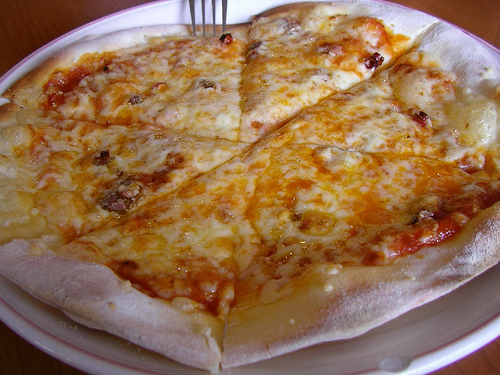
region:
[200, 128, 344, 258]
greasy pizza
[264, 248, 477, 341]
crust on a pizza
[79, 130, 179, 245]
burnt cheese on a pizza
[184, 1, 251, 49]
a fork into the pizza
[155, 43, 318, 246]
melted cheese on a pizza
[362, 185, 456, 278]
red sauce on a pizza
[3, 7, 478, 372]
a round cooked pizza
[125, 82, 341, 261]
sliced pizza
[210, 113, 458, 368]
a large slice of pizza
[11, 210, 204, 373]
a piece of white crust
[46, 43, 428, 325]
A cheese type pizza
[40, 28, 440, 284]
A pizza cut into six slices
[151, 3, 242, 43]
A fork for eating the pizza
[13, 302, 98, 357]
The plate holding the pizza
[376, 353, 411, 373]
A chip in the plate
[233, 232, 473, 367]
Crust of the pizza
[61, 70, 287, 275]
Cheese, dough and pizza saauce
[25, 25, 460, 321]
a round six piece pizza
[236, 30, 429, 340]
Half of the pizza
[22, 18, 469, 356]
a cheese pizza on a plate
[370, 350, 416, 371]
The pizza is sliced in six portions.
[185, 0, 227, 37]
The fork is ready to be used.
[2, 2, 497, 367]
The plate is white.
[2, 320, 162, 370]
The border of the plate has a pink stripe.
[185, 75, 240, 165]
The pizza is topped with cheese.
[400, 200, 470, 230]
The pizza is also topped with tomato.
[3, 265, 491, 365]
The pizza has a thin crust.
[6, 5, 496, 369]
The pizza is round.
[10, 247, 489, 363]
The crust is white.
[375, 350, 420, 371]
The plate is chipped.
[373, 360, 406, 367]
the plate is cracked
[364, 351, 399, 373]
the plate is cracked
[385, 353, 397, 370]
the plate is cracked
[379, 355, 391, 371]
the plate is cracked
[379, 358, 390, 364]
the plate is cracked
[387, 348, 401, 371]
the plate is cracked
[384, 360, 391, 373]
the plate is cracked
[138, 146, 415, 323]
cheese pizza cut in slices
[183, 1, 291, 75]
metal fork in pizza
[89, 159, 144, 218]
cheese bubbles in pizza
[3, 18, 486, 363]
pizza on white plate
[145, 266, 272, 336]
red sauce on pizza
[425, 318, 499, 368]
white plate on wood table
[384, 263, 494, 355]
pizza casting shadow on plate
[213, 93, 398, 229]
white and yellow cheese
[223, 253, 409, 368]
thin crust pizza dusted with flour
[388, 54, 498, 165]
bubbles in pizza